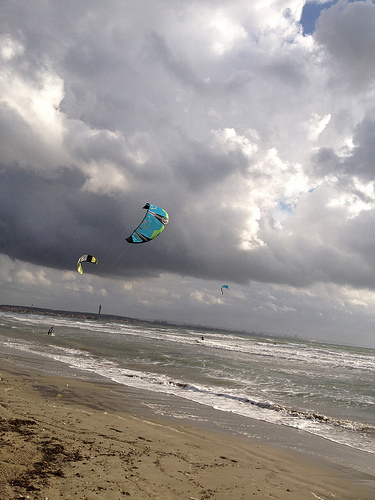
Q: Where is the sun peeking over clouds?
A: Peepking through.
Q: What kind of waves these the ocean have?
A: Smal waves.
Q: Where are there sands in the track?
A: Because of where the train pqssew vy.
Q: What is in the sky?
A: Many clouds.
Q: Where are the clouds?
A: In the sky.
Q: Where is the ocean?
A: Under the sky.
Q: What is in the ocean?
A: Some people.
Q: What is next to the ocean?
A: Sand.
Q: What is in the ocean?
A: Waves.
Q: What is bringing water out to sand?
A: Water waves.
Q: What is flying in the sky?
A: Two kites.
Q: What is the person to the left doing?
A: Standing in water.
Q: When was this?
A: Daytime.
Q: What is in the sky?
A: Parachutes.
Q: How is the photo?
A: Clear.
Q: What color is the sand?
A: Brown.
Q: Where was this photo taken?
A: Beachside.